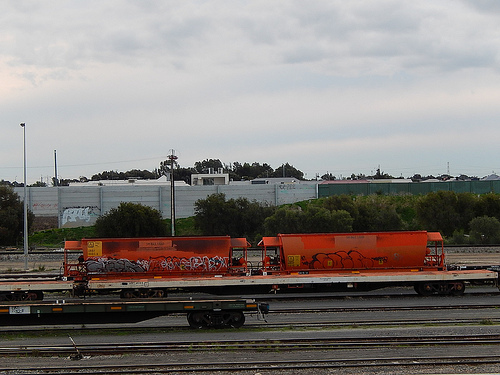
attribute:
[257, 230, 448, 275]
train car — metal, orange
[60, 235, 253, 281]
train car — metal, orange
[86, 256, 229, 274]
graffiti — white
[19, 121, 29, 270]
light post — grey, metal, tall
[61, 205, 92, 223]
graffiti — white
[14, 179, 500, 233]
wall — white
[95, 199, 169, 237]
bush — green, leafy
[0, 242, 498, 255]
tracks — wood, metal, brown, steel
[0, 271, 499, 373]
tracks — metal, brown, steel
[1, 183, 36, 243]
tree — green, leafy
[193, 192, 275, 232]
tree — green, leafy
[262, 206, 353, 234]
tree — green, leafy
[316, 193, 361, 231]
tree — green, leafy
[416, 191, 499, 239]
tree — green, leafy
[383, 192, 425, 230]
tree — green, leafy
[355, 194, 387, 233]
tree — green, leafy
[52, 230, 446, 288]
train — stopped, orange, red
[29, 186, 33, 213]
wall divider — grey, wooden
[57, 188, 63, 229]
wall divider — grey, wooden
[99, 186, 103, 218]
wall divider — grey, wooden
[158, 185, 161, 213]
wall divider — grey, wooden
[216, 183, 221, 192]
wall divider — grey, wooden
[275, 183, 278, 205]
wall divider — grey, wooden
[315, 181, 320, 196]
wall divider — grey, wooden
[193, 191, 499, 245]
trees — green, bushy, leafy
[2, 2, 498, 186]
sky — dark, cloudy, grey, overcast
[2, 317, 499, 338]
grass — green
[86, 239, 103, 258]
sticker — yellow